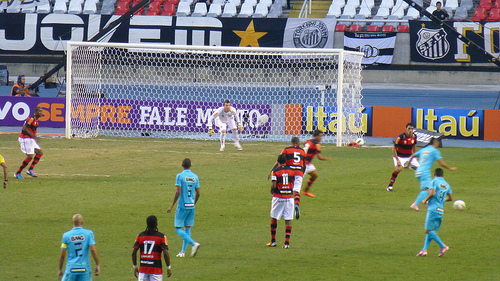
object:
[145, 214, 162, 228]
head